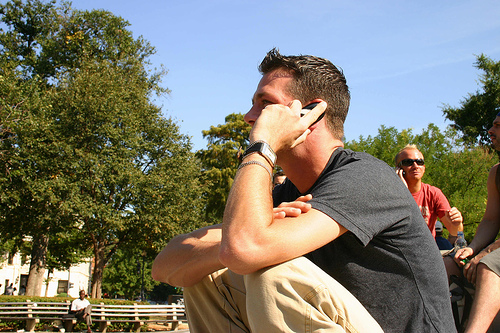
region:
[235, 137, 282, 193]
Man has watch on wrist.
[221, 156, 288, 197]
Man has bracelet on wrist.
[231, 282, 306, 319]
Man has on khaki pants.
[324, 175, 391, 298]
Man has on gray shirt.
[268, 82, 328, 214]
Man is holding black phone to ear.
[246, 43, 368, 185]
Man has short hair.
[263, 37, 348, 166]
Man has brown hair.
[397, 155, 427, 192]
Man has sunglasses on face.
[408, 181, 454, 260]
Man is wearing red shirt.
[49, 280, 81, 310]
Person sitting on bench.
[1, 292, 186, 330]
five white posts in a fence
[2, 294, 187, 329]
a white wooden fence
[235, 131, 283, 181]
a black band on a watch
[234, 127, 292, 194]
a rectangular face on a watch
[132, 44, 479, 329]
man with short brown hair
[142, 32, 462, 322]
man's hair is styled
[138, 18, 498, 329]
two men have cell phones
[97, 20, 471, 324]
two men talking on phones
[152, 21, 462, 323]
a man wearing a grey shirt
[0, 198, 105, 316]
a white building behind a tree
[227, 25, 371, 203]
A man with brown hair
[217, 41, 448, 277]
A man talking on a cell phone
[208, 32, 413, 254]
A man wearing a watch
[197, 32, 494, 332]
A man in a black shirt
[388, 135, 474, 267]
A man with blonde hair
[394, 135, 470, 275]
A man talking on a cell phone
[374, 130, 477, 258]
A man wearing sunglasses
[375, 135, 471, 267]
A man in a red shirt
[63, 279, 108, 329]
A person sitting on a bench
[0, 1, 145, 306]
Two trees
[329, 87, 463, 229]
Man on his phone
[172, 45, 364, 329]
a Caucasian man is on the phone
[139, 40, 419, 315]
a man having a conversation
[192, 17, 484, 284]
a man with gel in his hair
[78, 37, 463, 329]
a man is squatting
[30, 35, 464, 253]
people are outside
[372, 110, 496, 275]
a man is wearing sunglasses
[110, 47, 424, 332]
a man wearing a watch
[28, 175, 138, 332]
a man sitting on the bench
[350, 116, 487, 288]
a man facing the sun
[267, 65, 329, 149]
The man is holding a cell phone.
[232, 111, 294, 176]
The man is wearing a watch.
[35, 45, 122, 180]
The trees are green.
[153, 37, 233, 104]
The sky is blue.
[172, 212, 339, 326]
The man is wearing khaki pants.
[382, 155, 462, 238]
The man is wearing a red shirt.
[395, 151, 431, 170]
The man is wearing sunglasses.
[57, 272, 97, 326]
One man is sitting on benches.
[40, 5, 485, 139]
The sky is clear.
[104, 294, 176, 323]
The bench is grey.